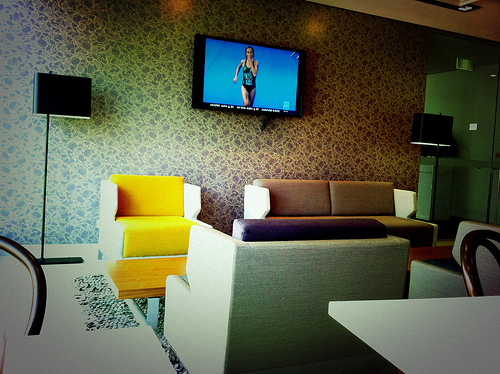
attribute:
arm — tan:
[238, 177, 274, 221]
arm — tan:
[388, 183, 423, 216]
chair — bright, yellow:
[103, 165, 210, 258]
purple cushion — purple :
[218, 210, 397, 241]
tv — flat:
[176, 27, 323, 125]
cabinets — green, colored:
[413, 62, 497, 237]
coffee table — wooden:
[95, 250, 224, 326]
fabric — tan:
[269, 180, 413, 237]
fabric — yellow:
[122, 180, 191, 251]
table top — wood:
[98, 256, 195, 298]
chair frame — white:
[90, 172, 130, 261]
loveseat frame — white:
[240, 183, 281, 218]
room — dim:
[21, 17, 436, 319]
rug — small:
[64, 273, 118, 327]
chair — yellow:
[64, 130, 245, 327]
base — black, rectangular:
[31, 239, 115, 269]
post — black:
[26, 127, 80, 241]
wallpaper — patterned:
[108, 71, 236, 159]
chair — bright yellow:
[96, 183, 203, 247]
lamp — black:
[399, 104, 491, 171]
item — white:
[364, 290, 492, 345]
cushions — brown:
[266, 183, 391, 225]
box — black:
[26, 70, 121, 182]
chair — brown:
[205, 171, 425, 245]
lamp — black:
[354, 106, 491, 240]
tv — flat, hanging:
[193, 33, 303, 119]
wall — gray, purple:
[8, 4, 500, 204]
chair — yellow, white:
[99, 172, 208, 259]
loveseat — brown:
[245, 178, 441, 246]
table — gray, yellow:
[102, 254, 198, 299]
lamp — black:
[33, 72, 97, 273]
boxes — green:
[418, 158, 499, 236]